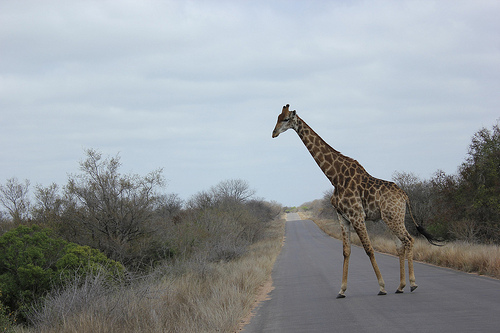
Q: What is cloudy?
A: The sky.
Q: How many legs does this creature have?
A: 4.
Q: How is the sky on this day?
A: Cloudy.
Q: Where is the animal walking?
A: On a road.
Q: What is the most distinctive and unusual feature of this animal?
A: Neck.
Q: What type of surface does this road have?
A: Asphalt.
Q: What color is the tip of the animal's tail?
A: Black.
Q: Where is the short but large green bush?
A: On the left.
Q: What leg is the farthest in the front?
A: Right.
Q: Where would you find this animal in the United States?
A: Zoo.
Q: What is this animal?
A: Giraffe.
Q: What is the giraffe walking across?
A: The road.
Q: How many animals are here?
A: One.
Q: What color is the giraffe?
A: Brown and yellow.